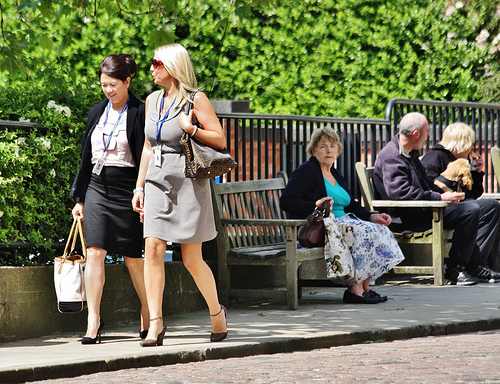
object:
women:
[70, 43, 228, 348]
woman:
[280, 123, 408, 304]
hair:
[166, 44, 204, 79]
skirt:
[83, 166, 143, 258]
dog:
[434, 157, 475, 196]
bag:
[296, 199, 331, 244]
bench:
[212, 170, 285, 259]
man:
[375, 107, 433, 194]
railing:
[221, 102, 305, 172]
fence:
[415, 96, 496, 117]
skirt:
[337, 216, 405, 281]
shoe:
[140, 321, 166, 346]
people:
[382, 115, 489, 219]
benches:
[233, 180, 433, 273]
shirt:
[327, 176, 356, 212]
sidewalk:
[256, 304, 405, 357]